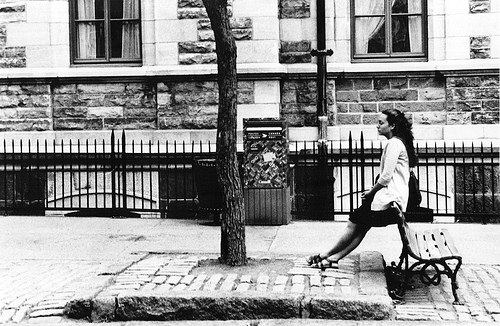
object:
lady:
[305, 108, 420, 273]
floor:
[2, 246, 60, 323]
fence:
[0, 131, 497, 218]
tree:
[210, 49, 248, 267]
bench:
[388, 199, 464, 307]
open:
[93, 21, 126, 63]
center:
[200, 124, 272, 264]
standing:
[393, 200, 471, 297]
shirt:
[370, 137, 418, 212]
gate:
[52, 129, 164, 214]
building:
[36, 31, 219, 130]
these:
[236, 211, 301, 244]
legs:
[320, 221, 355, 259]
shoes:
[305, 253, 332, 266]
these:
[244, 208, 375, 326]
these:
[129, 209, 246, 285]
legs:
[329, 226, 371, 269]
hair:
[374, 108, 423, 218]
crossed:
[307, 194, 375, 270]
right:
[327, 99, 365, 109]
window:
[342, 0, 427, 64]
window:
[75, 0, 145, 66]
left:
[6, 137, 58, 181]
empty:
[382, 221, 467, 299]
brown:
[399, 226, 410, 250]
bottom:
[220, 224, 247, 267]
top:
[202, 0, 240, 127]